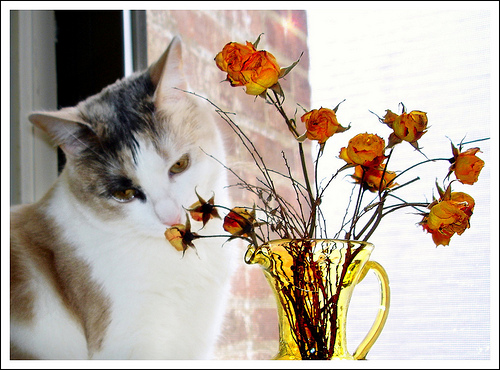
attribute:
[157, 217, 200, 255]
rosebud — orange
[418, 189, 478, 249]
rose — orange and yellow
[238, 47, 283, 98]
rose — orange and yellow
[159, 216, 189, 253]
rose — orange and yellow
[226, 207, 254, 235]
rose — orange and yellow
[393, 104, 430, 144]
rose — orange and yellow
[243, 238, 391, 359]
pitcher — clear, yellow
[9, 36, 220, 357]
cat — white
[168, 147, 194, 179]
eye — green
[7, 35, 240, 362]
cat — white, brown, and black, multi-colored, furry, white, tabby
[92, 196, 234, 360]
chest — white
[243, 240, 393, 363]
vase — yellow, glass, gold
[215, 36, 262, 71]
rose bud — orange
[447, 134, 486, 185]
rose bud — orange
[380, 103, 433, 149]
rose bud — orange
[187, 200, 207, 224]
rose bud — orange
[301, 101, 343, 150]
rose bud — orange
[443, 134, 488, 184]
rose bud — orange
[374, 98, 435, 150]
rose bud — orange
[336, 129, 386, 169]
rose bud — orange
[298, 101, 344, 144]
rose bud — orange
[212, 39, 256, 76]
rose bud — orange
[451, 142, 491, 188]
rose bud — orange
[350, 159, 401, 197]
rose bud — orange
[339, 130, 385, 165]
rose bud — orange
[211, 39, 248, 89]
rose bud — orange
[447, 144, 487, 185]
rose — orange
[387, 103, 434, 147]
rose — orange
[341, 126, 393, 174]
rose — orange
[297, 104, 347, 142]
rose — orange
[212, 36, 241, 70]
rose — orange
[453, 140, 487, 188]
rose — orange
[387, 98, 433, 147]
rose — orange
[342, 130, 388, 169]
rose — orange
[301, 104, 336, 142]
rose — orange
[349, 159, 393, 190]
rose — orange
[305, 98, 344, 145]
rose — orange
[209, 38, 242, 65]
rose — orange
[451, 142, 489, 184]
rose — orange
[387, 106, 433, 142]
rose — orange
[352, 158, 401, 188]
rose — orange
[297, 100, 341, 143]
rose — orange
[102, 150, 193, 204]
eyes — cat's, yellow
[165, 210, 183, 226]
nose — the cat's, pink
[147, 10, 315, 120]
wall — red, brick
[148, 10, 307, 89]
bricks — red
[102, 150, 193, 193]
eyes — cat's, beautiful, green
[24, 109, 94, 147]
ear — cat's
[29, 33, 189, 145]
ears — cat's, upturned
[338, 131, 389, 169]
flower — orange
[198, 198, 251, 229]
stem — black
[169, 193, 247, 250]
flowers — orange